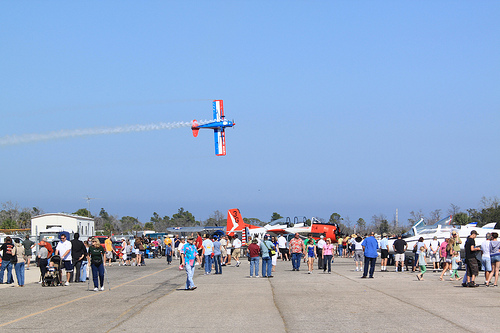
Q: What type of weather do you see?
A: It is clear.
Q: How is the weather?
A: It is clear.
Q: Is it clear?
A: Yes, it is clear.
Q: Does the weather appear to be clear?
A: Yes, it is clear.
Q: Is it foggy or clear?
A: It is clear.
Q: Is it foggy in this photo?
A: No, it is clear.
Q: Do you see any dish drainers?
A: No, there are no dish drainers.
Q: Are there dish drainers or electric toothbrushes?
A: No, there are no dish drainers or electric toothbrushes.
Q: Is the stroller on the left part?
A: Yes, the stroller is on the left of the image.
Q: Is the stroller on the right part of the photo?
A: No, the stroller is on the left of the image.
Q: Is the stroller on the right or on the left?
A: The stroller is on the left of the image.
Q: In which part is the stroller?
A: The stroller is on the left of the image.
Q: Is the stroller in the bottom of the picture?
A: Yes, the stroller is in the bottom of the image.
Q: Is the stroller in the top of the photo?
A: No, the stroller is in the bottom of the image.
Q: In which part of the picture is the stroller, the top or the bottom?
A: The stroller is in the bottom of the image.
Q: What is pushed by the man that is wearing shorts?
A: The stroller is pushed by the man.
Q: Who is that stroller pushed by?
A: The stroller is pushed by the man.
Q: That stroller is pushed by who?
A: The stroller is pushed by the man.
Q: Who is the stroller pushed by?
A: The stroller is pushed by the man.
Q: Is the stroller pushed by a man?
A: Yes, the stroller is pushed by a man.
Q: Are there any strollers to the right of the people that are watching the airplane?
A: Yes, there is a stroller to the right of the people.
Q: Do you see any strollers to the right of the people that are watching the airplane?
A: Yes, there is a stroller to the right of the people.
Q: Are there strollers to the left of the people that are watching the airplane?
A: No, the stroller is to the right of the people.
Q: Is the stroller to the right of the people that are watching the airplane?
A: Yes, the stroller is to the right of the people.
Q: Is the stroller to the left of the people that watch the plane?
A: No, the stroller is to the right of the people.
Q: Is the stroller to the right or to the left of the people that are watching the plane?
A: The stroller is to the right of the people.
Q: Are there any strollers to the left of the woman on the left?
A: Yes, there is a stroller to the left of the woman.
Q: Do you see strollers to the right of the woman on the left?
A: No, the stroller is to the left of the woman.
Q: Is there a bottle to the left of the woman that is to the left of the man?
A: No, there is a stroller to the left of the woman.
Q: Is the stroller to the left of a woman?
A: Yes, the stroller is to the left of a woman.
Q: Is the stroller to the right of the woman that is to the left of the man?
A: No, the stroller is to the left of the woman.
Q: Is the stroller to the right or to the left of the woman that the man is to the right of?
A: The stroller is to the left of the woman.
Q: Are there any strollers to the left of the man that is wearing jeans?
A: Yes, there is a stroller to the left of the man.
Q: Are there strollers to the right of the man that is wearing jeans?
A: No, the stroller is to the left of the man.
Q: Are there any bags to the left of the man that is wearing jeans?
A: No, there is a stroller to the left of the man.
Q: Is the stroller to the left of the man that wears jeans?
A: Yes, the stroller is to the left of the man.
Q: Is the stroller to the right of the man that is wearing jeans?
A: No, the stroller is to the left of the man.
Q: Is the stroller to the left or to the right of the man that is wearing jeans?
A: The stroller is to the left of the man.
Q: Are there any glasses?
A: No, there are no glasses.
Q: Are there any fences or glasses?
A: No, there are no glasses or fences.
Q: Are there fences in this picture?
A: No, there are no fences.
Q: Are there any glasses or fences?
A: No, there are no fences or glasses.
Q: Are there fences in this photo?
A: No, there are no fences.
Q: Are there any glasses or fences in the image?
A: No, there are no fences or glasses.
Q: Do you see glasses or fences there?
A: No, there are no fences or glasses.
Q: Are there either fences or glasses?
A: No, there are no fences or glasses.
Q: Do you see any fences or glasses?
A: No, there are no fences or glasses.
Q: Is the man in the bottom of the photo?
A: Yes, the man is in the bottom of the image.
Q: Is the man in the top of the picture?
A: No, the man is in the bottom of the image.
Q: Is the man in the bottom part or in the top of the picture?
A: The man is in the bottom of the image.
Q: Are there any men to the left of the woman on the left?
A: Yes, there is a man to the left of the woman.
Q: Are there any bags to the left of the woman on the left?
A: No, there is a man to the left of the woman.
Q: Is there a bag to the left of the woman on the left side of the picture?
A: No, there is a man to the left of the woman.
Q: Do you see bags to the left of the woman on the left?
A: No, there is a man to the left of the woman.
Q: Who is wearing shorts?
A: The man is wearing shorts.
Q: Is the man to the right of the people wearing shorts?
A: Yes, the man is wearing shorts.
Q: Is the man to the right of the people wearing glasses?
A: No, the man is wearing shorts.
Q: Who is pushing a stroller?
A: The man is pushing a stroller.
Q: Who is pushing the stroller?
A: The man is pushing a stroller.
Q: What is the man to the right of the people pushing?
A: The man is pushing a stroller.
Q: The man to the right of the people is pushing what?
A: The man is pushing a stroller.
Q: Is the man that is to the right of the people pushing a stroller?
A: Yes, the man is pushing a stroller.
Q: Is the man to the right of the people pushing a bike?
A: No, the man is pushing a stroller.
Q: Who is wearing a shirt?
A: The man is wearing a shirt.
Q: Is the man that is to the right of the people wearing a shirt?
A: Yes, the man is wearing a shirt.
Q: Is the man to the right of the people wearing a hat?
A: No, the man is wearing a shirt.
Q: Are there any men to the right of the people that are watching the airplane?
A: Yes, there is a man to the right of the people.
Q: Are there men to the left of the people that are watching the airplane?
A: No, the man is to the right of the people.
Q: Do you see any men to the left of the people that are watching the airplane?
A: No, the man is to the right of the people.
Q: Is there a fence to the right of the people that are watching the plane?
A: No, there is a man to the right of the people.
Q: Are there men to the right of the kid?
A: Yes, there is a man to the right of the kid.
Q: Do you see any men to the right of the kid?
A: Yes, there is a man to the right of the kid.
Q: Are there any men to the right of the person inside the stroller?
A: Yes, there is a man to the right of the kid.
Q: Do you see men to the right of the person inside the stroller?
A: Yes, there is a man to the right of the kid.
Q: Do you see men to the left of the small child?
A: No, the man is to the right of the kid.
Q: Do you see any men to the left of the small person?
A: No, the man is to the right of the kid.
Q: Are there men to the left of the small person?
A: No, the man is to the right of the kid.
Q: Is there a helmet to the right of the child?
A: No, there is a man to the right of the child.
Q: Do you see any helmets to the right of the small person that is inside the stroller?
A: No, there is a man to the right of the child.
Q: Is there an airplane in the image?
A: Yes, there is an airplane.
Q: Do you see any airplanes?
A: Yes, there is an airplane.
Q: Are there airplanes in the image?
A: Yes, there is an airplane.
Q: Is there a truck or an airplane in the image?
A: Yes, there is an airplane.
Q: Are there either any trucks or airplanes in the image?
A: Yes, there is an airplane.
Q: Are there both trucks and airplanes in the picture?
A: No, there is an airplane but no trucks.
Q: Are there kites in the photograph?
A: No, there are no kites.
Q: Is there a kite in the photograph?
A: No, there are no kites.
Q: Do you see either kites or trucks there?
A: No, there are no kites or trucks.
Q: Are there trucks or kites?
A: No, there are no kites or trucks.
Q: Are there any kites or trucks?
A: No, there are no kites or trucks.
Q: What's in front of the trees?
A: The airplane is in front of the trees.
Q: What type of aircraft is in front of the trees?
A: The aircraft is an airplane.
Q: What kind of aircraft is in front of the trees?
A: The aircraft is an airplane.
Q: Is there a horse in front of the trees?
A: No, there is an airplane in front of the trees.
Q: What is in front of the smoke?
A: The airplane is in front of the smoke.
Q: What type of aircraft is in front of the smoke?
A: The aircraft is an airplane.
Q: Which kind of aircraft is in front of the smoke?
A: The aircraft is an airplane.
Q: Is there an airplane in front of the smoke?
A: Yes, there is an airplane in front of the smoke.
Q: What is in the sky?
A: The airplane is in the sky.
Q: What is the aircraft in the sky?
A: The aircraft is an airplane.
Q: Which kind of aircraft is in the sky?
A: The aircraft is an airplane.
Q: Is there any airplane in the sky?
A: Yes, there is an airplane in the sky.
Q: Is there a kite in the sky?
A: No, there is an airplane in the sky.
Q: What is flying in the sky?
A: The plane is flying in the sky.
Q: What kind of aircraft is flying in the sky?
A: The aircraft is an airplane.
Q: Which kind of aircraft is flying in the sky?
A: The aircraft is an airplane.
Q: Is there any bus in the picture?
A: Yes, there is a bus.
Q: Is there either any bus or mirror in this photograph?
A: Yes, there is a bus.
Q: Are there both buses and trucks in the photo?
A: No, there is a bus but no trucks.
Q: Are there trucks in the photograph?
A: No, there are no trucks.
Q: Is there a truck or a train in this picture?
A: No, there are no trucks or trains.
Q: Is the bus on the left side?
A: Yes, the bus is on the left of the image.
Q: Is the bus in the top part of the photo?
A: No, the bus is in the bottom of the image.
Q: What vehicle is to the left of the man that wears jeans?
A: The vehicle is a bus.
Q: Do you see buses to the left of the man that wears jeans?
A: Yes, there is a bus to the left of the man.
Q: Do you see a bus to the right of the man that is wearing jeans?
A: No, the bus is to the left of the man.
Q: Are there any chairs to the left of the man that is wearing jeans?
A: No, there is a bus to the left of the man.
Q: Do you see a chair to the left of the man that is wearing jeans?
A: No, there is a bus to the left of the man.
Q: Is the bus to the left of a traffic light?
A: No, the bus is to the left of a man.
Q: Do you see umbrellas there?
A: No, there are no umbrellas.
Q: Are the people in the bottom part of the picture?
A: Yes, the people are in the bottom of the image.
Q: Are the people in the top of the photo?
A: No, the people are in the bottom of the image.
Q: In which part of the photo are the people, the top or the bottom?
A: The people are in the bottom of the image.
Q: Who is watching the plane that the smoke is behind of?
A: The people are watching the plane.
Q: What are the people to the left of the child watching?
A: The people are watching the plane.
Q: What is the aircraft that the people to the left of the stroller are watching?
A: The aircraft is an airplane.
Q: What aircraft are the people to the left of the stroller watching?
A: The people are watching the airplane.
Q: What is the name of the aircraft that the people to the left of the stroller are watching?
A: The aircraft is an airplane.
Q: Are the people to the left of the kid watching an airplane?
A: Yes, the people are watching an airplane.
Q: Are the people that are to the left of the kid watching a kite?
A: No, the people are watching an airplane.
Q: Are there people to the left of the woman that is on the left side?
A: Yes, there are people to the left of the woman.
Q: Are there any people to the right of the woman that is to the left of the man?
A: No, the people are to the left of the woman.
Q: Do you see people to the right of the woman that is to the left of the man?
A: No, the people are to the left of the woman.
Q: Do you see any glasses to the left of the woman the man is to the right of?
A: No, there are people to the left of the woman.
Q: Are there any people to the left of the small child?
A: Yes, there are people to the left of the child.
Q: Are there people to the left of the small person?
A: Yes, there are people to the left of the child.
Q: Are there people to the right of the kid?
A: No, the people are to the left of the kid.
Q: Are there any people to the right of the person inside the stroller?
A: No, the people are to the left of the kid.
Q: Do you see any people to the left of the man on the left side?
A: Yes, there are people to the left of the man.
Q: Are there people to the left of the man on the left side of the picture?
A: Yes, there are people to the left of the man.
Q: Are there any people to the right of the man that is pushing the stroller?
A: No, the people are to the left of the man.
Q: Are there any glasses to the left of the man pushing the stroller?
A: No, there are people to the left of the man.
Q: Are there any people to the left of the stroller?
A: Yes, there are people to the left of the stroller.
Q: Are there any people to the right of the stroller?
A: No, the people are to the left of the stroller.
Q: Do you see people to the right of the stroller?
A: No, the people are to the left of the stroller.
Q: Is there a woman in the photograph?
A: Yes, there is a woman.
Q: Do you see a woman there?
A: Yes, there is a woman.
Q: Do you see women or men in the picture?
A: Yes, there is a woman.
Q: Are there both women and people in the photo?
A: Yes, there are both a woman and people.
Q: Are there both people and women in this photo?
A: Yes, there are both a woman and people.